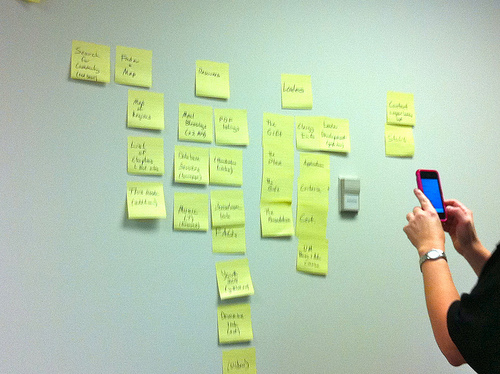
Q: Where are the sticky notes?
A: Wall.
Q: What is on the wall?
A: Sticky notes.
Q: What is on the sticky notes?
A: Writing.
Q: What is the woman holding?
A: Phone.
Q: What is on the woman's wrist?
A: Watch.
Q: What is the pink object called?
A: Phone case.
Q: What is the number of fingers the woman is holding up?
A: 1.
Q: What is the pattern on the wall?
A: Solid.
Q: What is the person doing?
A: Taking a photo with a phone.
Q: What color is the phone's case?
A: Red.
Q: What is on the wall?
A: Post-its.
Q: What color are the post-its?
A: Yellow.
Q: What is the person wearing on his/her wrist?
A: A watch.